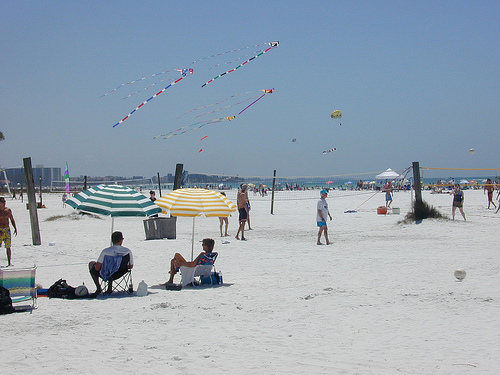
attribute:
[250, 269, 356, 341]
sand — white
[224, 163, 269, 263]
man — standing, wearing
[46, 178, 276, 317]
people — sitting, relaxing, playing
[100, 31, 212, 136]
skit — flying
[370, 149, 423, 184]
umbrella — white, large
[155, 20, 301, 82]
kite — flying, long, colorful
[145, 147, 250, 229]
umbrella — striped, stripes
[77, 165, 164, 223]
umbrella — green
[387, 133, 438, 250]
post — thick, wooden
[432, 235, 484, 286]
ball — volley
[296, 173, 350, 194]
ocean — blue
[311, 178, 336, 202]
hat — blue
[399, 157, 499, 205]
net — volleyball